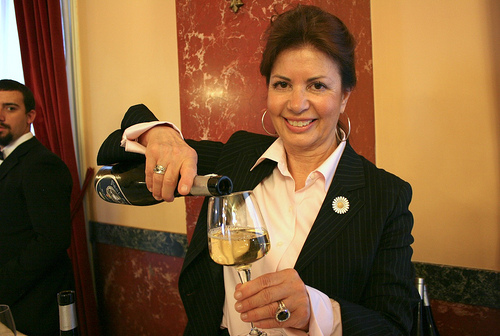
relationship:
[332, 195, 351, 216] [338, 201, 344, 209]
daisy has yellow center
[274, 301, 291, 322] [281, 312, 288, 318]
ring has stone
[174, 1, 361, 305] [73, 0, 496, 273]
marble on wall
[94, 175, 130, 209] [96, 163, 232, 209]
label on bottle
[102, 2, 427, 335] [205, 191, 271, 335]
woman holding glass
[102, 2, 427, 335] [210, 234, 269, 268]
woman pouring wine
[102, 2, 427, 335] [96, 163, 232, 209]
woman holding bottle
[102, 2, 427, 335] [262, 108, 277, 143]
woman wearing earing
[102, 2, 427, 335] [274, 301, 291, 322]
woman wearing ring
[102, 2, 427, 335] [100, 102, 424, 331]
woman wearing jacket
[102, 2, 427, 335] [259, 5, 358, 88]
woman has hair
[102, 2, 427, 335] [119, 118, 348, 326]
woman wearing shirt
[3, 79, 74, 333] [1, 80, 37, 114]
man with hair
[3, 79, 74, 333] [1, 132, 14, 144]
man has beard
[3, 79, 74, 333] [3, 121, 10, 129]
man has mustache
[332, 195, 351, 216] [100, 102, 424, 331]
daisy on jacket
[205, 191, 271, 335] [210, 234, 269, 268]
glass with wine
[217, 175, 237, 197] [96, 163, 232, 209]
top of bottle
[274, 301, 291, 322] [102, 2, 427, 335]
ring on woman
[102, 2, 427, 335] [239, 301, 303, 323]
woman has finger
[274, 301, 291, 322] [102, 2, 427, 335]
ring worn by woman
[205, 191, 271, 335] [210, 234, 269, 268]
glass of wine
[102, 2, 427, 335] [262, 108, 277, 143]
woman has earing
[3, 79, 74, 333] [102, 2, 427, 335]
man watching woman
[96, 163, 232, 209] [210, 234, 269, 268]
bottle of wine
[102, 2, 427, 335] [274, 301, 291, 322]
woman has ring